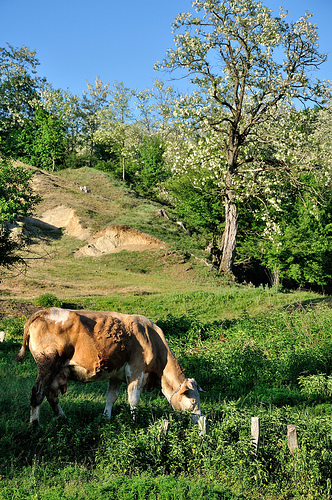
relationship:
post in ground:
[243, 413, 261, 463] [231, 448, 310, 491]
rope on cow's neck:
[163, 384, 194, 407] [157, 355, 186, 400]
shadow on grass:
[202, 336, 331, 404] [194, 274, 312, 378]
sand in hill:
[75, 220, 150, 252] [77, 158, 165, 279]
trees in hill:
[109, 135, 195, 197] [77, 158, 165, 279]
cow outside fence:
[12, 305, 227, 449] [198, 408, 317, 464]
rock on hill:
[75, 180, 104, 197] [77, 158, 165, 279]